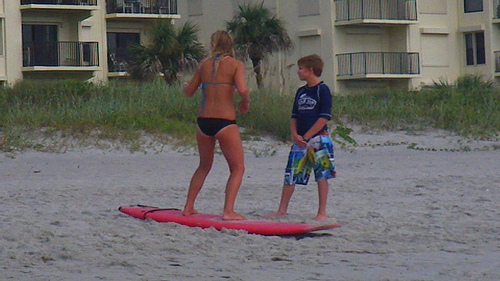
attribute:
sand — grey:
[79, 198, 242, 279]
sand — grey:
[4, 154, 133, 279]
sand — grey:
[36, 157, 135, 276]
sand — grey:
[97, 214, 170, 277]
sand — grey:
[74, 162, 164, 279]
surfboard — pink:
[106, 185, 348, 255]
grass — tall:
[6, 78, 159, 141]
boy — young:
[279, 49, 349, 229]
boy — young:
[269, 48, 349, 228]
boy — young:
[275, 48, 345, 231]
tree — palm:
[220, 6, 296, 107]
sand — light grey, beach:
[13, 147, 483, 264]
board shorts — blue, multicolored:
[269, 139, 364, 212]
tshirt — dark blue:
[273, 87, 341, 133]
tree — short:
[213, 0, 310, 92]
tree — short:
[113, 3, 209, 92]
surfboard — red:
[128, 169, 357, 269]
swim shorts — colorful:
[254, 109, 360, 189]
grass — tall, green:
[25, 74, 215, 138]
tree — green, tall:
[202, 8, 297, 84]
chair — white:
[85, 63, 112, 79]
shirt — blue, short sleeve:
[275, 63, 352, 157]